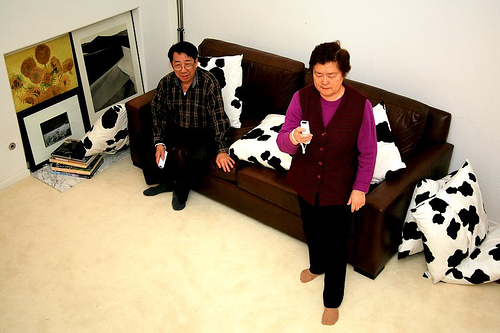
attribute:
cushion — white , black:
[231, 158, 306, 220]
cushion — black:
[208, 118, 259, 183]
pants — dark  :
[302, 192, 355, 307]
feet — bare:
[296, 258, 346, 327]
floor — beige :
[114, 236, 254, 313]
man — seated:
[137, 40, 236, 210]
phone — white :
[290, 117, 320, 155]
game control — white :
[298, 118, 312, 146]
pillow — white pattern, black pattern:
[402, 153, 497, 287]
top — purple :
[316, 97, 344, 122]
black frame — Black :
[4, 43, 114, 189]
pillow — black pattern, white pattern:
[403, 184, 483, 251]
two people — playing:
[147, 41, 399, 324]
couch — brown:
[102, 35, 474, 287]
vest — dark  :
[295, 84, 365, 201]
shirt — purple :
[277, 84, 387, 195]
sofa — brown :
[126, 35, 456, 273]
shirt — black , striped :
[152, 67, 229, 147]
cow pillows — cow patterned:
[443, 220, 499, 289]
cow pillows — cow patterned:
[414, 149, 491, 285]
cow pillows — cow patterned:
[392, 160, 459, 257]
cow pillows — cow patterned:
[89, 92, 136, 162]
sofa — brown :
[113, 22, 455, 277]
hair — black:
[165, 40, 195, 56]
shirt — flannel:
[148, 59, 232, 158]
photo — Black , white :
[34, 113, 75, 146]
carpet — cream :
[9, 143, 498, 331]